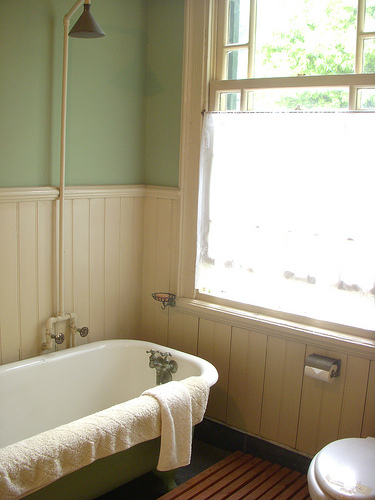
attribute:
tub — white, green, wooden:
[0, 343, 242, 457]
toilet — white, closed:
[301, 406, 374, 499]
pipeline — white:
[54, 41, 70, 321]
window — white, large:
[195, 21, 374, 339]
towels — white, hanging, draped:
[118, 399, 211, 446]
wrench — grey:
[77, 323, 98, 344]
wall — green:
[90, 62, 154, 145]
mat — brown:
[193, 438, 286, 500]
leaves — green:
[273, 21, 374, 83]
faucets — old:
[149, 347, 183, 379]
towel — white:
[145, 393, 201, 446]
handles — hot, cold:
[40, 323, 111, 352]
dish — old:
[145, 291, 198, 325]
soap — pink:
[160, 290, 172, 305]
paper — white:
[277, 349, 350, 390]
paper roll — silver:
[301, 343, 336, 374]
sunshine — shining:
[258, 73, 370, 165]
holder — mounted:
[304, 353, 344, 374]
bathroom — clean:
[12, 9, 374, 499]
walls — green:
[91, 92, 180, 137]